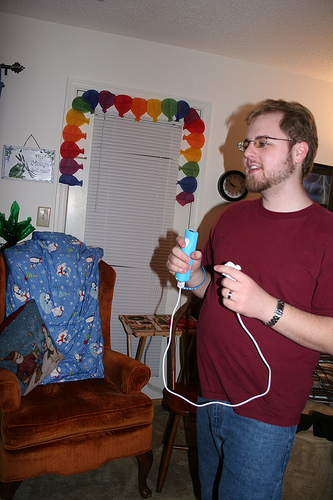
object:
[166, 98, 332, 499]
man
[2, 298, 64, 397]
pillow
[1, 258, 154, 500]
chair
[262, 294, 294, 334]
wrist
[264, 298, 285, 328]
watch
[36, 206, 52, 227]
light switch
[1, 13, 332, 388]
wall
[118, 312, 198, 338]
tray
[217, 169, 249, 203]
clock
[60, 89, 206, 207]
balloon decoration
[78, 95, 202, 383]
window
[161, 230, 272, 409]
wii remote control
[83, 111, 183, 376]
blinds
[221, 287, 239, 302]
finger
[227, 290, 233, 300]
ring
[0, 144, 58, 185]
sign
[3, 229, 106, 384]
blanket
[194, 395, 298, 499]
jeans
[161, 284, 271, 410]
wire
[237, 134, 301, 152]
eyeglasses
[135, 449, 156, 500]
leg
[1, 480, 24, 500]
leg